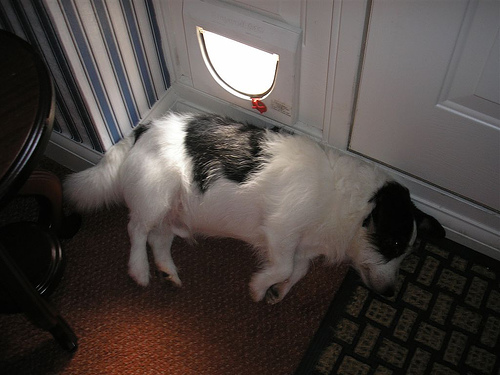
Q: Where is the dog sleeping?
A: On the floor.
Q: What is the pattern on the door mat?
A: Squares.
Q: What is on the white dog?
A: Black patches.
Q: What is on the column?
A: Blue stripe pattern.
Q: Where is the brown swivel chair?
A: In the corner.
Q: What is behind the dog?
A: A locked pet door.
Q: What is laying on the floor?
A: A dog.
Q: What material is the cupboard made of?
A: The cupboard is wooden.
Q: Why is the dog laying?
A: The dog is resting.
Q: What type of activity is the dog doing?
A: The dog is resting.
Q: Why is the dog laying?
A: The dog is resting.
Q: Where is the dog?
A: The dog is lying down on the floor.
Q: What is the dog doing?
A: Lying on the floor.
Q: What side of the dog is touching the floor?
A: Left side.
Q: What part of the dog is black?
A: Top of head.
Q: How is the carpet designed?
A: Brown with small yellowish dots.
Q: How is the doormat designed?
A: Dark brown with beige patterns.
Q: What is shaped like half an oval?
A: Door slot.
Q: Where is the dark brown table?
A: In front of dog's tail.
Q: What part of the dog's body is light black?
A: Top back.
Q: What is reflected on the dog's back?
A: Sunlight.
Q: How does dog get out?
A: Dog door.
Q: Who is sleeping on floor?
A: A dog.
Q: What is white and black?
A: Dog.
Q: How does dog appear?
A: Lonely.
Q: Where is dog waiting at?
A: The door.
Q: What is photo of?
A: Dog waiting at door.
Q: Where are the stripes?
A: On wall.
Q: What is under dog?
A: Carpet.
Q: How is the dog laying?
A: On its side.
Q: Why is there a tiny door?
A: For the dog.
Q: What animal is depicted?
A: Dog.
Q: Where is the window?
A: Dog door.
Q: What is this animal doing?
A: Laying down.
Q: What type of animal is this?
A: Dog.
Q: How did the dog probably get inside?
A: Through dog door.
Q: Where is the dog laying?
A: On floor.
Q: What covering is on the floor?
A: Carpet.